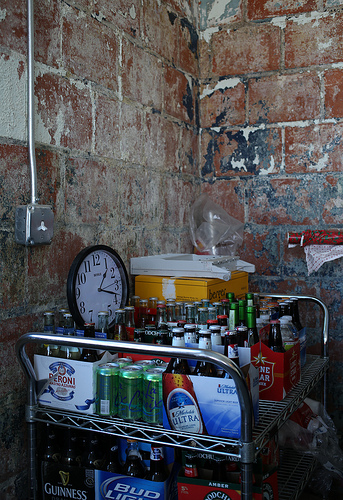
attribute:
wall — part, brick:
[0, 0, 341, 431]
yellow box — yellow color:
[134, 269, 248, 301]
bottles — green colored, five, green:
[225, 291, 258, 327]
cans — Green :
[96, 357, 166, 425]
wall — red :
[33, 2, 338, 198]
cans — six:
[95, 356, 176, 418]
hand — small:
[94, 264, 114, 289]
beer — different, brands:
[31, 291, 307, 499]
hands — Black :
[78, 256, 136, 307]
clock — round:
[63, 240, 132, 337]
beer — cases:
[147, 361, 269, 449]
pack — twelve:
[93, 437, 175, 498]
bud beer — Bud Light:
[95, 437, 174, 498]